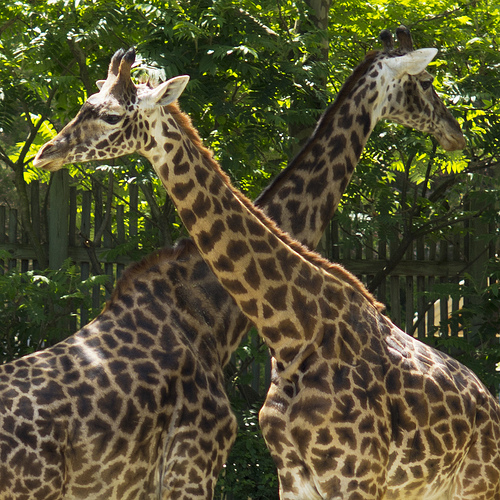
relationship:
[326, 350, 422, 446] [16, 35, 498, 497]
lines on giraffe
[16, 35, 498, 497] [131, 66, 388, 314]
giraffe has brown mane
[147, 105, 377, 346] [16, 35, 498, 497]
neck of giraffe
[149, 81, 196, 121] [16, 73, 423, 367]
ear of giraffe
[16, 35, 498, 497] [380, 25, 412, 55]
giraffe with protrusions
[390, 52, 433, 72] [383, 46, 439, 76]
back of ear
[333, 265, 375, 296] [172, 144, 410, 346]
hairs on neck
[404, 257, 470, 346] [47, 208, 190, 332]
object through fence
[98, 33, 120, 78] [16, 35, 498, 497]
horn on giraffe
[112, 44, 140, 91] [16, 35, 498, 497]
horn on giraffe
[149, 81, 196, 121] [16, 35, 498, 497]
ear on giraffe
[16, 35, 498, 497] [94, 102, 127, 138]
giraffe has eye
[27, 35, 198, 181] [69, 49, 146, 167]
head of photo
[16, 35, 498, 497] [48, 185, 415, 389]
giraffe are two in number